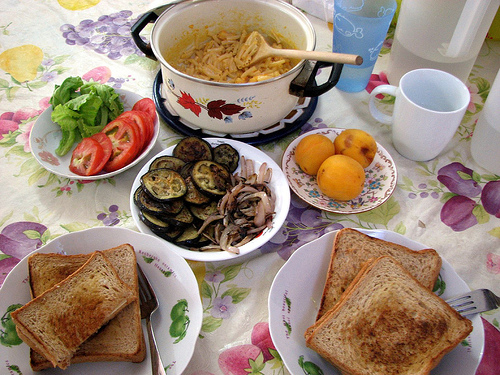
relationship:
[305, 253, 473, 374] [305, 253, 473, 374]
toast of toast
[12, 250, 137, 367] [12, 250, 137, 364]
toast of toast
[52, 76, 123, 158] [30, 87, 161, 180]
lettuce in a bowl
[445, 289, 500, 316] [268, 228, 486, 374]
fork on a bowl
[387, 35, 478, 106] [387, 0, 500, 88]
water in a pitcher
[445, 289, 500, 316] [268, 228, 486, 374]
fork on bowl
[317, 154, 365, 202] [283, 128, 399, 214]
fruit on plate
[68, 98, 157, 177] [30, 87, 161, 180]
tomato in a bowl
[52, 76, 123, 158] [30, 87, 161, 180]
lettuce in bowl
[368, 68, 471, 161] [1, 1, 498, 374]
cup on table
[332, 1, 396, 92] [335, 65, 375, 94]
cup of water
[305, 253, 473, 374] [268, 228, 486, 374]
toast in bowl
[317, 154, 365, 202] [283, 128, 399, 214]
fruit sitting on plate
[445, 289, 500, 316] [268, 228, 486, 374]
fork resting on bowl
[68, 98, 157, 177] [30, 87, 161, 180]
tomato in bowl